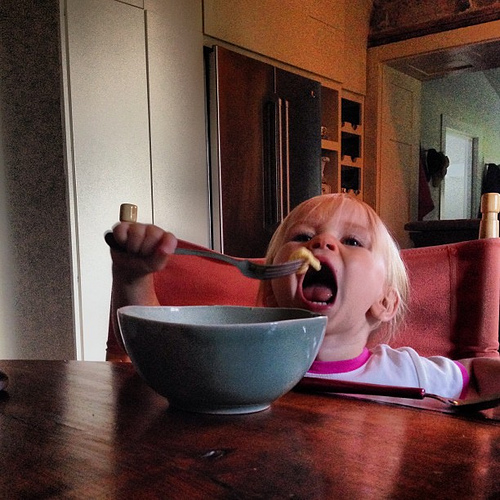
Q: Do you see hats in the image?
A: Yes, there is a hat.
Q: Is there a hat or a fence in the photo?
A: Yes, there is a hat.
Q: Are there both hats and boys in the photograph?
A: Yes, there are both a hat and a boy.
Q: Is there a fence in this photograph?
A: No, there are no fences.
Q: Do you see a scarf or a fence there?
A: No, there are no fences or scarves.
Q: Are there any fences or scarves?
A: No, there are no fences or scarves.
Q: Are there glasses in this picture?
A: No, there are no glasses.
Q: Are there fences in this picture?
A: No, there are no fences.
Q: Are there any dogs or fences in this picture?
A: No, there are no fences or dogs.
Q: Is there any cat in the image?
A: No, there are no cats.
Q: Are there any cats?
A: No, there are no cats.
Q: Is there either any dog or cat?
A: No, there are no cats or dogs.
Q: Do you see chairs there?
A: Yes, there is a chair.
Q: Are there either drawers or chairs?
A: Yes, there is a chair.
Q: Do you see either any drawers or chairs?
A: Yes, there is a chair.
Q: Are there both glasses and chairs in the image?
A: No, there is a chair but no glasses.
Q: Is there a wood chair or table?
A: Yes, there is a wood chair.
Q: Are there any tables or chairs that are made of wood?
A: Yes, the chair is made of wood.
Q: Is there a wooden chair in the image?
A: Yes, there is a wood chair.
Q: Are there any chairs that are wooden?
A: Yes, there is a chair that is wooden.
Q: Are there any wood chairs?
A: Yes, there is a chair that is made of wood.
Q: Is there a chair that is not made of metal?
A: Yes, there is a chair that is made of wood.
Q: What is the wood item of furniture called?
A: The piece of furniture is a chair.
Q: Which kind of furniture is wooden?
A: The furniture is a chair.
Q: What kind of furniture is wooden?
A: The furniture is a chair.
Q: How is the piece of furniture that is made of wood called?
A: The piece of furniture is a chair.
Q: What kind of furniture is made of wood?
A: The furniture is a chair.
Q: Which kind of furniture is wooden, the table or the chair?
A: The chair is wooden.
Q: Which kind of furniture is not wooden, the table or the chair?
A: The table is not wooden.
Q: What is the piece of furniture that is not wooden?
A: The piece of furniture is a table.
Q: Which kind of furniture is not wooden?
A: The furniture is a table.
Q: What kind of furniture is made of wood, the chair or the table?
A: The chair is made of wood.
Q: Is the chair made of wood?
A: Yes, the chair is made of wood.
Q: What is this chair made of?
A: The chair is made of wood.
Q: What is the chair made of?
A: The chair is made of wood.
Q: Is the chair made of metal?
A: No, the chair is made of wood.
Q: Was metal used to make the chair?
A: No, the chair is made of wood.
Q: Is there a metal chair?
A: No, there is a chair but it is made of wood.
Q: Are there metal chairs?
A: No, there is a chair but it is made of wood.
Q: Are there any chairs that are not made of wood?
A: No, there is a chair but it is made of wood.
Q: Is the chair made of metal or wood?
A: The chair is made of wood.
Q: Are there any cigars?
A: No, there are no cigars.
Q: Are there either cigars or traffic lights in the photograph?
A: No, there are no cigars or traffic lights.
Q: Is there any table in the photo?
A: Yes, there is a table.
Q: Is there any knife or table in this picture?
A: Yes, there is a table.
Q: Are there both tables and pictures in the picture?
A: No, there is a table but no pictures.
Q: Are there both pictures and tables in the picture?
A: No, there is a table but no pictures.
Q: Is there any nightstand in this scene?
A: No, there are no nightstands.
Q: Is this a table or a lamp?
A: This is a table.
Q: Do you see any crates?
A: No, there are no crates.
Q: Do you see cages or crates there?
A: No, there are no crates or cages.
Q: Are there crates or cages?
A: No, there are no crates or cages.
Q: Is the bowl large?
A: Yes, the bowl is large.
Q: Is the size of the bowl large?
A: Yes, the bowl is large.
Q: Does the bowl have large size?
A: Yes, the bowl is large.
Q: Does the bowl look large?
A: Yes, the bowl is large.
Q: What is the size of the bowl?
A: The bowl is large.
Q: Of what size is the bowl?
A: The bowl is large.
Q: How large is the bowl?
A: The bowl is large.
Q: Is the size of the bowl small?
A: No, the bowl is large.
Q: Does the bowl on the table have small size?
A: No, the bowl is large.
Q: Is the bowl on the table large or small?
A: The bowl is large.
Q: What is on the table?
A: The bowl is on the table.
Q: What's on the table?
A: The bowl is on the table.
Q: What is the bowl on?
A: The bowl is on the table.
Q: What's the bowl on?
A: The bowl is on the table.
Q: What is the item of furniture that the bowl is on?
A: The piece of furniture is a table.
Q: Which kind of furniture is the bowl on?
A: The bowl is on the table.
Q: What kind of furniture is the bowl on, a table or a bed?
A: The bowl is on a table.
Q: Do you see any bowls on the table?
A: Yes, there is a bowl on the table.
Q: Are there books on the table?
A: No, there is a bowl on the table.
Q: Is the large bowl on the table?
A: Yes, the bowl is on the table.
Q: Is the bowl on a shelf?
A: No, the bowl is on the table.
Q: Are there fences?
A: No, there are no fences.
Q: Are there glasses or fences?
A: No, there are no fences or glasses.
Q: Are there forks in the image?
A: Yes, there is a fork.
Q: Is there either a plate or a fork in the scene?
A: Yes, there is a fork.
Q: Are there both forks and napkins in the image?
A: No, there is a fork but no napkins.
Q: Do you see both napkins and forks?
A: No, there is a fork but no napkins.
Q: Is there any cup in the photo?
A: No, there are no cups.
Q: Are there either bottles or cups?
A: No, there are no cups or bottles.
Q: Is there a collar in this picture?
A: Yes, there is a collar.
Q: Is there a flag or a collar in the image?
A: Yes, there is a collar.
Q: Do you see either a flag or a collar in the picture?
A: Yes, there is a collar.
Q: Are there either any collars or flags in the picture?
A: Yes, there is a collar.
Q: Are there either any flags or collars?
A: Yes, there is a collar.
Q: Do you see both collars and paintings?
A: No, there is a collar but no paintings.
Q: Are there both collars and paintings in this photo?
A: No, there is a collar but no paintings.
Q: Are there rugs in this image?
A: No, there are no rugs.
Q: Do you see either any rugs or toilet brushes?
A: No, there are no rugs or toilet brushes.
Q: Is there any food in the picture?
A: Yes, there is food.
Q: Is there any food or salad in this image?
A: Yes, there is food.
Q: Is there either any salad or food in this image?
A: Yes, there is food.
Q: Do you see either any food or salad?
A: Yes, there is food.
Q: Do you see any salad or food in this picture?
A: Yes, there is food.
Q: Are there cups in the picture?
A: No, there are no cups.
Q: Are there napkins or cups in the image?
A: No, there are no cups or napkins.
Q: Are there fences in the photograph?
A: No, there are no fences.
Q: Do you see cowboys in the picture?
A: No, there are no cowboys.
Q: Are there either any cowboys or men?
A: No, there are no cowboys or men.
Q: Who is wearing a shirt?
A: The boy is wearing a shirt.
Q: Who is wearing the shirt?
A: The boy is wearing a shirt.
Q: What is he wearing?
A: The boy is wearing a shirt.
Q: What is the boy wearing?
A: The boy is wearing a shirt.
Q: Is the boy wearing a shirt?
A: Yes, the boy is wearing a shirt.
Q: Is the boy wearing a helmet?
A: No, the boy is wearing a shirt.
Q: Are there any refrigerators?
A: Yes, there is a refrigerator.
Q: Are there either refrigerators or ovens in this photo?
A: Yes, there is a refrigerator.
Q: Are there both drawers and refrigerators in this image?
A: No, there is a refrigerator but no drawers.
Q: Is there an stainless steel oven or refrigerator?
A: Yes, there is a stainless steel refrigerator.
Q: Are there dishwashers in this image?
A: No, there are no dishwashers.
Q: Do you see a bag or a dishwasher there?
A: No, there are no dishwashers or bags.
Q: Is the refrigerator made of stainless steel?
A: Yes, the refrigerator is made of stainless steel.